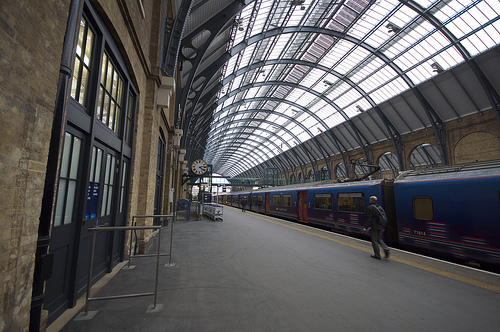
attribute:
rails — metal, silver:
[132, 198, 197, 240]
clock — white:
[174, 147, 219, 179]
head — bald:
[367, 192, 377, 202]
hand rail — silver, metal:
[87, 224, 156, 311]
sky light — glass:
[205, 0, 497, 177]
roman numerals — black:
[200, 159, 203, 163]